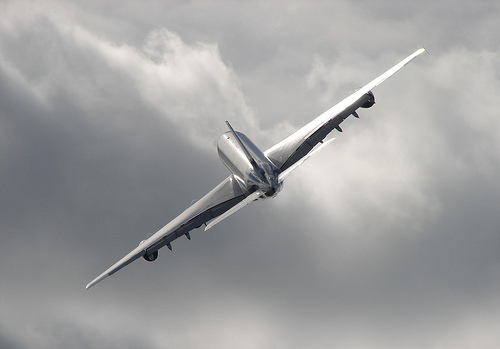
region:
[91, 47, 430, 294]
Silver air plane in the sky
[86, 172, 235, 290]
left wing of airplane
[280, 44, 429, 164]
Red wing of the plane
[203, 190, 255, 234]
Left tail wing of plane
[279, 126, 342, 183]
Right tail wing of plane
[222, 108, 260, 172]
Silver tail of plane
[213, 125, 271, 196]
Silver body of plane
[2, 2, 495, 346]
Grey and white clouds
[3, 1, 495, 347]
A sky full of clouds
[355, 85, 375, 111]
Engine of the right wing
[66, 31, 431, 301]
airplane flying in sky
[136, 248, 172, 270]
black wheel on bottom of plane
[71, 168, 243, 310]
wing on plane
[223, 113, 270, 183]
tail on top of plane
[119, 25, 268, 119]
white cloud in grey sky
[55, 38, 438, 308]
plane hanging at an angle in sky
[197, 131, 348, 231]
horizontal tail of plane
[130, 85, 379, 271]
two black wheels on bottom of plane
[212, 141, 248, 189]
black shadow on side of plane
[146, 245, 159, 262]
metal bolt in middle of plane wheel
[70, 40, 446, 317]
plane in mid air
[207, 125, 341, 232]
back wings of a plane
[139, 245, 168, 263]
turbines of a plane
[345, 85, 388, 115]
turbines of a plane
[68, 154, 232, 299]
left wing of a plane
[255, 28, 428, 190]
right wing of a plane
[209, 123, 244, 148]
front of a plane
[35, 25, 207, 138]
sky full of clouds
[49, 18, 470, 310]
a plane tilted in the sky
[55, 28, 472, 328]
plane flying in the sky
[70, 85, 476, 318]
a variety of cloud colors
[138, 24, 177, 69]
a thin whisp of clouds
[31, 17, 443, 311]
an overcast sky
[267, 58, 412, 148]
light reflecting off a plane wing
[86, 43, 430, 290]
a reflective, silver plane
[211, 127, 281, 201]
the body of a plane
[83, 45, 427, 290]
a plane in flight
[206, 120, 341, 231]
the tail of a plane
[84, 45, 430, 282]
a pair of silver wings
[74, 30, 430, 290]
a form of speedy transportation